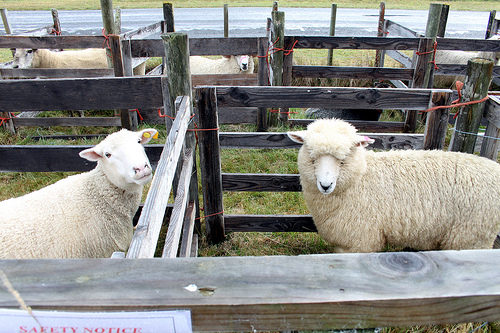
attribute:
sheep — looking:
[288, 108, 500, 249]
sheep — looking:
[2, 117, 162, 261]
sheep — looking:
[151, 37, 253, 100]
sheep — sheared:
[9, 38, 154, 125]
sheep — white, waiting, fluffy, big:
[7, 17, 500, 267]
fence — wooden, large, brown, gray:
[4, 6, 499, 326]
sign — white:
[3, 302, 193, 332]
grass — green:
[6, 44, 491, 262]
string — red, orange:
[4, 17, 491, 238]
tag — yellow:
[141, 128, 162, 141]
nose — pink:
[133, 160, 152, 174]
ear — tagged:
[135, 125, 159, 147]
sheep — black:
[301, 59, 395, 124]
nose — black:
[316, 180, 335, 191]